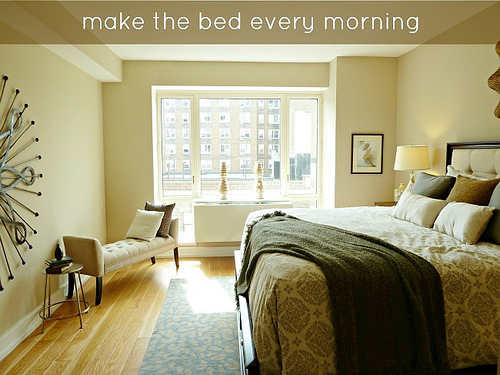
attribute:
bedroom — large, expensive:
[30, 32, 491, 343]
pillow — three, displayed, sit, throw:
[370, 162, 480, 255]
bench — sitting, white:
[168, 180, 318, 251]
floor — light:
[75, 289, 151, 373]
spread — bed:
[202, 212, 411, 352]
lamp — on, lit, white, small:
[357, 120, 440, 214]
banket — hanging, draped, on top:
[207, 213, 431, 352]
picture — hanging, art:
[330, 112, 427, 196]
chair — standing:
[10, 249, 95, 372]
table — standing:
[368, 188, 402, 209]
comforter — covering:
[289, 205, 453, 320]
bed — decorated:
[231, 132, 492, 322]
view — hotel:
[145, 77, 333, 188]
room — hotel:
[50, 24, 471, 320]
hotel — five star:
[52, 38, 456, 323]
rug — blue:
[142, 270, 237, 360]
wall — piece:
[343, 116, 414, 198]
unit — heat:
[192, 195, 242, 247]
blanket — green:
[221, 188, 329, 254]